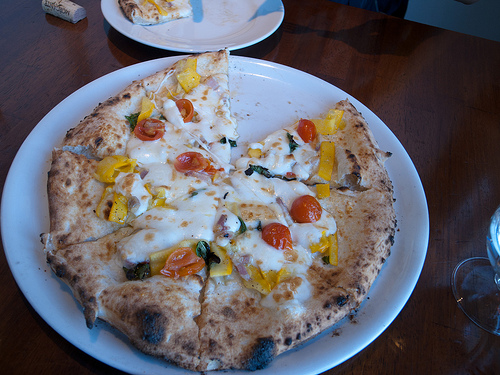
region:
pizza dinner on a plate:
[0, 79, 448, 372]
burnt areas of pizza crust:
[135, 305, 276, 371]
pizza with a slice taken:
[45, 50, 396, 370]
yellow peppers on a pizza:
[92, 153, 138, 223]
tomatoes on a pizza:
[135, 116, 210, 173]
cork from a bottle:
[38, 0, 88, 22]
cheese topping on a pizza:
[140, 141, 263, 237]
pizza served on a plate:
[96, 0, 284, 45]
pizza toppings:
[91, 155, 339, 271]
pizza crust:
[56, 274, 378, 356]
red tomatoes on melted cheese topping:
[131, 105, 175, 155]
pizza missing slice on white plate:
[4, 45, 421, 367]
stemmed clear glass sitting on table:
[445, 177, 497, 350]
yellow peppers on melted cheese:
[302, 131, 356, 209]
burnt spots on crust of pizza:
[128, 295, 229, 366]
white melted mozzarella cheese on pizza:
[149, 205, 208, 252]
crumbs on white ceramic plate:
[234, 75, 302, 144]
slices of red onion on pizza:
[273, 187, 298, 231]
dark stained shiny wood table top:
[405, 82, 483, 147]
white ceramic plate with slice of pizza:
[91, 0, 303, 63]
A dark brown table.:
[389, 40, 466, 119]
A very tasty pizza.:
[42, 28, 415, 347]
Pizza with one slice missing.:
[125, 49, 394, 176]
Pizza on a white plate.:
[230, 79, 402, 191]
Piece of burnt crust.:
[130, 299, 181, 352]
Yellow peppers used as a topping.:
[308, 132, 343, 189]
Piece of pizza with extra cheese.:
[121, 185, 221, 262]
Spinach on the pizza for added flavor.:
[190, 235, 223, 269]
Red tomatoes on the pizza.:
[285, 188, 328, 228]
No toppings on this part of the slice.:
[337, 195, 383, 273]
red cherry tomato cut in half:
[277, 178, 360, 242]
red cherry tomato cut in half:
[130, 95, 166, 155]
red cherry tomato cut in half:
[295, 99, 312, 142]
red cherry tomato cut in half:
[173, 139, 220, 194]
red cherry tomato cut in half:
[255, 205, 305, 271]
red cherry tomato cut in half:
[170, 72, 200, 132]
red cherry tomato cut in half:
[150, 230, 205, 290]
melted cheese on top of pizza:
[140, 198, 241, 283]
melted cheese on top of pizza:
[135, 115, 201, 176]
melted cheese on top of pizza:
[122, 161, 197, 202]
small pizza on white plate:
[32, 50, 354, 348]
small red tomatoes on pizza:
[292, 197, 336, 237]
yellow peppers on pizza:
[98, 153, 138, 178]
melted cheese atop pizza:
[181, 152, 270, 269]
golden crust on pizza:
[133, 299, 166, 351]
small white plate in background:
[110, 7, 289, 74]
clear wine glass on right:
[448, 219, 494, 327]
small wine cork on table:
[29, 0, 89, 32]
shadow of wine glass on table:
[310, 13, 402, 70]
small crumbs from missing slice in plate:
[234, 86, 284, 120]